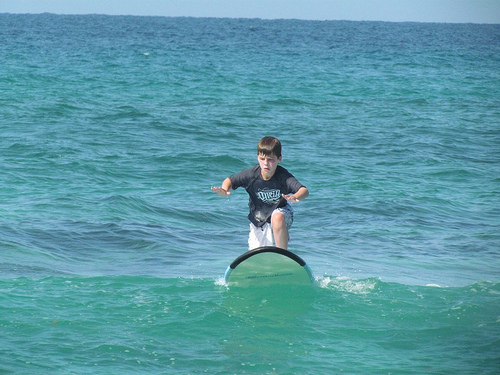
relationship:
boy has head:
[211, 134, 311, 252] [254, 133, 284, 181]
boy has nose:
[211, 134, 311, 252] [263, 158, 269, 167]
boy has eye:
[211, 134, 311, 252] [260, 155, 266, 163]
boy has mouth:
[211, 134, 311, 252] [262, 165, 273, 172]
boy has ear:
[211, 134, 311, 252] [275, 153, 284, 165]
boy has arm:
[211, 134, 311, 252] [279, 167, 310, 212]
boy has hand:
[211, 134, 311, 252] [279, 190, 303, 209]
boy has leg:
[211, 134, 311, 252] [268, 204, 294, 253]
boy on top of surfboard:
[211, 134, 311, 252] [222, 245, 319, 291]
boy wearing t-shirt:
[211, 134, 311, 252] [226, 166, 308, 230]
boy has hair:
[211, 134, 311, 252] [256, 134, 285, 159]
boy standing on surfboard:
[211, 134, 311, 252] [222, 245, 319, 291]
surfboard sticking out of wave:
[222, 245, 319, 291] [2, 267, 499, 324]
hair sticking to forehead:
[256, 134, 285, 159] [256, 145, 284, 155]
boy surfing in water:
[211, 134, 311, 252] [1, 15, 499, 375]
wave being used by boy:
[2, 267, 499, 324] [211, 134, 311, 252]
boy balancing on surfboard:
[211, 134, 311, 252] [222, 245, 319, 291]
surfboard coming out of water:
[222, 245, 319, 291] [1, 15, 499, 375]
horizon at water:
[1, 9, 499, 33] [1, 15, 499, 375]